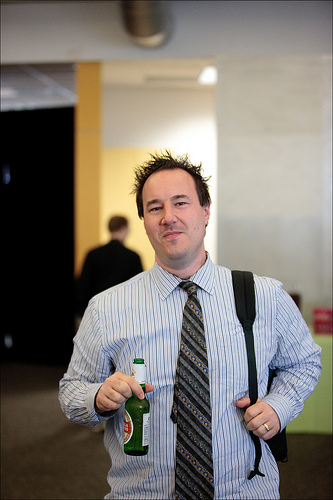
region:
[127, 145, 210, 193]
Man's spiked, black hair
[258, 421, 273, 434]
Man's gold wedding band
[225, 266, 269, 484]
Black backpack shoulder strap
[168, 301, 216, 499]
Ornate black and grey tie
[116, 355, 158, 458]
Green glass beer bottle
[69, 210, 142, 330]
Blurry man walking in background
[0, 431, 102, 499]
Brown lobby carpet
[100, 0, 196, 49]
Metal ventilation tube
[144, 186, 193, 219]
Man's eyes and nose bridge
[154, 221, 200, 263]
Man's smirk and stubble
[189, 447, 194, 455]
the tie is black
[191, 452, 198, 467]
the tie is black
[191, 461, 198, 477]
the tie is black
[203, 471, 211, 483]
the tie is black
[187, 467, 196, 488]
the tie is black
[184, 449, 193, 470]
the tie is black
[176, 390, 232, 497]
a man wearing a tie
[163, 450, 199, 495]
a man wearing a tie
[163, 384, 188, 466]
a man wearing a tie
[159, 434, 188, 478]
a man wearing a tie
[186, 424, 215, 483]
a man wearing a tie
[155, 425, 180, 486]
a man wearing a tie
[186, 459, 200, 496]
a man wearing a tie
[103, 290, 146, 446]
A bottle of beer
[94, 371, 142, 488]
A bottle of beer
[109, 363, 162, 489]
A bottle of beer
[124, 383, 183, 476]
A bottle of beer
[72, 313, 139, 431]
A bottle of beer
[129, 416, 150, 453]
A bottle of beer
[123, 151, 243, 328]
Man with brown spiky hair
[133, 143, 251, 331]
Man smiling slightly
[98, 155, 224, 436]
Man in a tie holding a beer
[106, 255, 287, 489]
Blue and white striped shirt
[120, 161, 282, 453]
Man with a back pack on left shoulder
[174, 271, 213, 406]
Dark multi-colored tie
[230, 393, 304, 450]
Ring on a man's hand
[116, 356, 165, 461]
Green beer bottle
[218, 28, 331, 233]
White wall in building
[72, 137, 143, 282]
Man wearing a black dress shirt